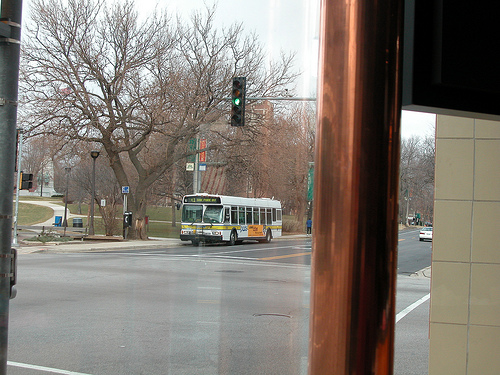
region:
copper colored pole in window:
[303, 52, 395, 350]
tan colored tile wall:
[445, 137, 498, 306]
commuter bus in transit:
[174, 183, 332, 260]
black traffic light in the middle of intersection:
[219, 64, 262, 154]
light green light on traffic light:
[230, 96, 245, 113]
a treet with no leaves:
[48, 12, 224, 166]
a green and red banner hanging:
[182, 141, 235, 180]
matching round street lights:
[57, 147, 129, 241]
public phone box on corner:
[115, 200, 139, 235]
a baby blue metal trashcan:
[49, 208, 65, 229]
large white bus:
[173, 190, 282, 244]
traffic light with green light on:
[222, 68, 327, 119]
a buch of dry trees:
[18, 21, 432, 238]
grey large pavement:
[0, 209, 442, 370]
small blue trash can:
[54, 217, 62, 230]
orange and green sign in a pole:
[185, 134, 210, 219]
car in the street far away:
[420, 221, 435, 239]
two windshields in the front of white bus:
[182, 204, 222, 224]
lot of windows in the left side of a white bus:
[223, 204, 285, 224]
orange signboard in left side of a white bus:
[249, 224, 268, 235]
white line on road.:
[22, 357, 49, 372]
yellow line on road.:
[266, 250, 292, 265]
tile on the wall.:
[455, 175, 477, 279]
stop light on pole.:
[230, 79, 244, 121]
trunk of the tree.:
[133, 173, 147, 211]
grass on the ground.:
[23, 207, 39, 219]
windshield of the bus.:
[207, 207, 220, 219]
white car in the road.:
[422, 227, 429, 238]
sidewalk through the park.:
[44, 200, 68, 215]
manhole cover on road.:
[257, 308, 290, 325]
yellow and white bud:
[183, 191, 283, 242]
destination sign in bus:
[184, 196, 219, 205]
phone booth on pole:
[123, 186, 131, 237]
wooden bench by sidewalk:
[18, 226, 90, 244]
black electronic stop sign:
[232, 77, 247, 125]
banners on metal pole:
[188, 129, 208, 174]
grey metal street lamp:
[90, 151, 97, 241]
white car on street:
[418, 225, 431, 240]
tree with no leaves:
[24, 4, 284, 249]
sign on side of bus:
[241, 223, 265, 237]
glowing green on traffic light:
[225, 91, 250, 117]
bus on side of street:
[175, 188, 289, 252]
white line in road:
[395, 294, 426, 324]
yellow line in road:
[255, 249, 307, 271]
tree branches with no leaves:
[100, 26, 228, 98]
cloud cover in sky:
[261, 7, 313, 39]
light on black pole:
[82, 145, 107, 202]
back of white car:
[415, 219, 439, 248]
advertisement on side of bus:
[236, 221, 272, 242]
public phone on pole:
[117, 205, 142, 236]